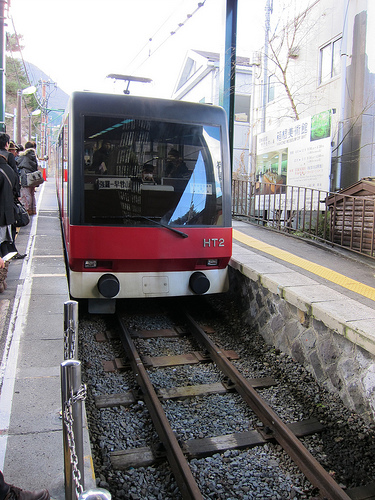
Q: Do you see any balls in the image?
A: No, there are no balls.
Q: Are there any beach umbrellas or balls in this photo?
A: No, there are no balls or beach umbrellas.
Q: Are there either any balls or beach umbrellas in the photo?
A: No, there are no balls or beach umbrellas.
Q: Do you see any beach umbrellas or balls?
A: No, there are no balls or beach umbrellas.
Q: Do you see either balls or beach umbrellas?
A: No, there are no balls or beach umbrellas.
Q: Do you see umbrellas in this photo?
A: No, there are no umbrellas.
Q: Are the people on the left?
A: Yes, the people are on the left of the image.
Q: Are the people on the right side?
A: No, the people are on the left of the image.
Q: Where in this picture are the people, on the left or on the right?
A: The people are on the left of the image.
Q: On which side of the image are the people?
A: The people are on the left of the image.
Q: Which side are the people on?
A: The people are on the left of the image.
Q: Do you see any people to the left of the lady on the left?
A: Yes, there are people to the left of the lady.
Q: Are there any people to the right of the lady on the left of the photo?
A: No, the people are to the left of the lady.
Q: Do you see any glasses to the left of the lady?
A: No, there are people to the left of the lady.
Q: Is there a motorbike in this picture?
A: No, there are no motorcycles.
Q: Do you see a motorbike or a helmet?
A: No, there are no motorcycles or helmets.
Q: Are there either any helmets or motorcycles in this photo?
A: No, there are no motorcycles or helmets.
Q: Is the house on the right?
A: Yes, the house is on the right of the image.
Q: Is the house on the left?
A: No, the house is on the right of the image.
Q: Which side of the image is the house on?
A: The house is on the right of the image.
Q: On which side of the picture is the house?
A: The house is on the right of the image.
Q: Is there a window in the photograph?
A: Yes, there is a window.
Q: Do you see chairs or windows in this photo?
A: Yes, there is a window.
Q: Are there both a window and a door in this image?
A: No, there is a window but no doors.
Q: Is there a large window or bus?
A: Yes, there is a large window.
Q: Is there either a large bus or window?
A: Yes, there is a large window.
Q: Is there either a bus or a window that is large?
A: Yes, the window is large.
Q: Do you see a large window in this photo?
A: Yes, there is a large window.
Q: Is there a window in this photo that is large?
A: Yes, there is a window that is large.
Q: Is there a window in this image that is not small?
A: Yes, there is a large window.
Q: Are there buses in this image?
A: No, there are no buses.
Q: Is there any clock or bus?
A: No, there are no buses or clocks.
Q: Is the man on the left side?
A: Yes, the man is on the left of the image.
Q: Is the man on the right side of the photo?
A: No, the man is on the left of the image.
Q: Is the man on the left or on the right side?
A: The man is on the left of the image.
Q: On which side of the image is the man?
A: The man is on the left of the image.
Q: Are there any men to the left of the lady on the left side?
A: Yes, there is a man to the left of the lady.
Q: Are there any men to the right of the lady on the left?
A: No, the man is to the left of the lady.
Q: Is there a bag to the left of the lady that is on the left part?
A: No, there is a man to the left of the lady.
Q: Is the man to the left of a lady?
A: Yes, the man is to the left of a lady.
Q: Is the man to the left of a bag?
A: No, the man is to the left of a lady.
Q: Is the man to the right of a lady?
A: No, the man is to the left of a lady.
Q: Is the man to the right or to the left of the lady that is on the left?
A: The man is to the left of the lady.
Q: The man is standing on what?
A: The man is standing on the platform.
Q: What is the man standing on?
A: The man is standing on the platform.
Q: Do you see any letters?
A: Yes, there are letters.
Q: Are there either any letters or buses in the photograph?
A: Yes, there are letters.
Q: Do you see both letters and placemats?
A: No, there are letters but no placemats.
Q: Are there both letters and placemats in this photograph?
A: No, there are letters but no placemats.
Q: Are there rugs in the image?
A: No, there are no rugs.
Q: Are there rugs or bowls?
A: No, there are no rugs or bowls.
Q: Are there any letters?
A: Yes, there are letters.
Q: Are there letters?
A: Yes, there are letters.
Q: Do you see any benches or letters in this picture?
A: Yes, there are letters.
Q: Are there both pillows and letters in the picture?
A: No, there are letters but no pillows.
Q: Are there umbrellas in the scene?
A: No, there are no umbrellas.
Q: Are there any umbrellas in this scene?
A: No, there are no umbrellas.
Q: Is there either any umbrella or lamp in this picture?
A: No, there are no umbrellas or lamps.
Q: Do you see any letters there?
A: Yes, there are letters.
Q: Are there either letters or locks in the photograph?
A: Yes, there are letters.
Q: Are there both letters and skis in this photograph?
A: No, there are letters but no skis.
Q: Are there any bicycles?
A: No, there are no bicycles.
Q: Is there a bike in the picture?
A: No, there are no bikes.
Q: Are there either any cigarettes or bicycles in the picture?
A: No, there are no bicycles or cigarettes.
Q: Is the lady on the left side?
A: Yes, the lady is on the left of the image.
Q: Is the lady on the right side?
A: No, the lady is on the left of the image.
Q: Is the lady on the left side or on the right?
A: The lady is on the left of the image.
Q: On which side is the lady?
A: The lady is on the left of the image.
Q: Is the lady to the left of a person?
A: No, the lady is to the right of a person.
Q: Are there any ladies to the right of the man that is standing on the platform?
A: Yes, there is a lady to the right of the man.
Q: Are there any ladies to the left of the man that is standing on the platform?
A: No, the lady is to the right of the man.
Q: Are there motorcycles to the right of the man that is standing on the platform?
A: No, there is a lady to the right of the man.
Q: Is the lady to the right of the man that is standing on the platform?
A: Yes, the lady is to the right of the man.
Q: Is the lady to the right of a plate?
A: No, the lady is to the right of the man.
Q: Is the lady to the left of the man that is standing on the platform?
A: No, the lady is to the right of the man.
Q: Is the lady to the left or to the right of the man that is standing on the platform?
A: The lady is to the right of the man.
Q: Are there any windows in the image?
A: Yes, there is a window.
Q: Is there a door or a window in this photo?
A: Yes, there is a window.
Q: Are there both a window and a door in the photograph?
A: No, there is a window but no doors.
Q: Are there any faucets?
A: No, there are no faucets.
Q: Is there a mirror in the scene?
A: No, there are no mirrors.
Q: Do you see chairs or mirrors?
A: No, there are no mirrors or chairs.